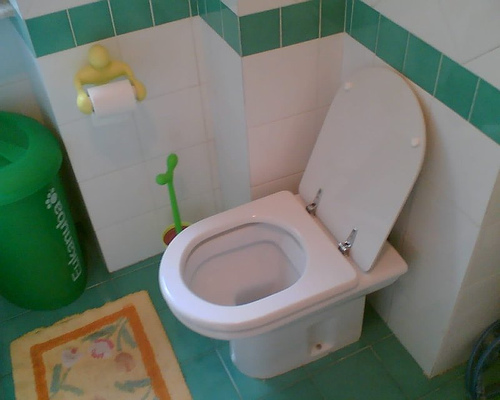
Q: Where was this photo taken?
A: In a bathroom.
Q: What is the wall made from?
A: Tiles.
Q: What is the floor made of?
A: Tiles.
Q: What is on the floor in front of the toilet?
A: A small rug.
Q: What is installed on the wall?
A: White porcelain wall tiles.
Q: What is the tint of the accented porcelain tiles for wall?
A: Green.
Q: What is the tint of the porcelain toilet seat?
A: White.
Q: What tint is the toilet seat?
A: White.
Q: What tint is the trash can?
A: Green.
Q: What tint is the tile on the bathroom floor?
A: Green.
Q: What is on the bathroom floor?
A: A throw rug.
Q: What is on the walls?
A: A row of green tiles.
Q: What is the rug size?
A: Small.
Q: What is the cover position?
A: Up.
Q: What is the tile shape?
A: Square.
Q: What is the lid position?
A: Oepn.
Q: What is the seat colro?
A: White.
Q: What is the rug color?
A: Yellow.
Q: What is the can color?
A: Green.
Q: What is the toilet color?
A: White.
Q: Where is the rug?
A: Floor.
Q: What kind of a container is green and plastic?
A: It is a garbage container in a restroom.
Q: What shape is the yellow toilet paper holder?
A: It is in the shape of a man.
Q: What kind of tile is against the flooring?
A: The tile is a bright aqua green.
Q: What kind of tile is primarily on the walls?
A: There is shiny white tile on the walls.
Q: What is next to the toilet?
A: It is a toilet brush.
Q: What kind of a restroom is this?
A: This is a restroom in a private residence.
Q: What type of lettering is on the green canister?
A: There is white lettering on the green canister.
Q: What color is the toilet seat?
A: White.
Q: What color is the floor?
A: Green.